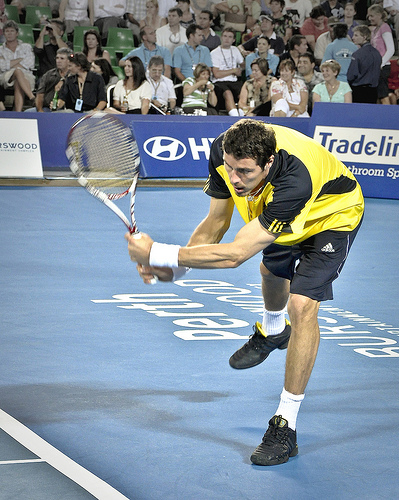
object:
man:
[127, 115, 366, 467]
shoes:
[248, 413, 300, 465]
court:
[0, 184, 398, 497]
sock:
[274, 386, 305, 431]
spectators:
[310, 58, 353, 111]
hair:
[222, 118, 277, 171]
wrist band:
[148, 241, 181, 268]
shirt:
[201, 120, 365, 249]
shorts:
[262, 208, 366, 302]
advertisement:
[305, 100, 397, 201]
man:
[146, 56, 178, 116]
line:
[0, 407, 129, 500]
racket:
[62, 113, 158, 287]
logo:
[320, 242, 336, 253]